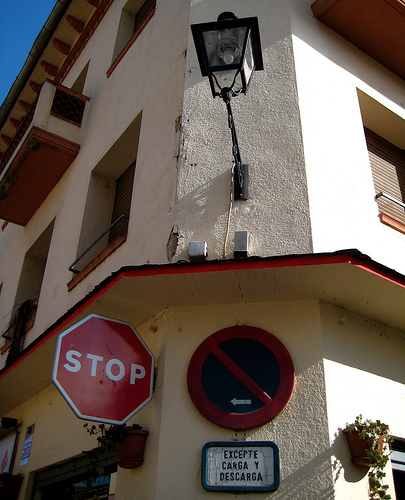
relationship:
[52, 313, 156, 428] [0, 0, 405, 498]
red sign on building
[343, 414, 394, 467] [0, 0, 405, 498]
flower pot on side of building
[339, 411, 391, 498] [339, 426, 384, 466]
potted plant growing from pot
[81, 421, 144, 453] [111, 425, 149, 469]
plant growing from pot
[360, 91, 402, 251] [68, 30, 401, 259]
window on building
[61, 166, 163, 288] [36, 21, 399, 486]
balcony on building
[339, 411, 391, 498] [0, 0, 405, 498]
potted plant attached to building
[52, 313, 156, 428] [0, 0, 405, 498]
red sign mounted to building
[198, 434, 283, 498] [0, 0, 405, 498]
sign on a building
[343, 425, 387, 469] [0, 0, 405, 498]
flower pot attached to a building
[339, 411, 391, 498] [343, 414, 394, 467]
potted plant growing in a flower pot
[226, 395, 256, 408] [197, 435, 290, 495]
arrow on a sign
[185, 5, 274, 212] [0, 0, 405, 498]
black light mounted to a building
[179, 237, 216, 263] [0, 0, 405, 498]
electrical box on a building